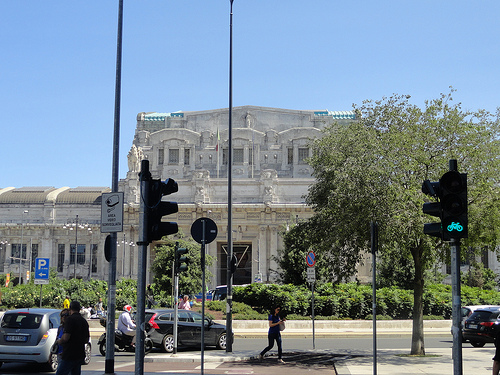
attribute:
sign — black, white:
[100, 190, 125, 237]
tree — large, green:
[315, 97, 498, 371]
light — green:
[420, 157, 470, 240]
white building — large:
[125, 103, 369, 220]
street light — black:
[139, 156, 181, 250]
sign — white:
[358, 215, 381, 265]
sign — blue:
[30, 244, 50, 286]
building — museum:
[8, 101, 498, 316]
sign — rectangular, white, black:
[99, 191, 124, 233]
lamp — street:
[416, 160, 477, 374]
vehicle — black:
[460, 305, 497, 345]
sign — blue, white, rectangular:
[22, 237, 74, 279]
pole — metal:
[451, 239, 462, 373]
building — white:
[3, 109, 386, 283]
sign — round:
[185, 212, 226, 258]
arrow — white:
[35, 270, 49, 277]